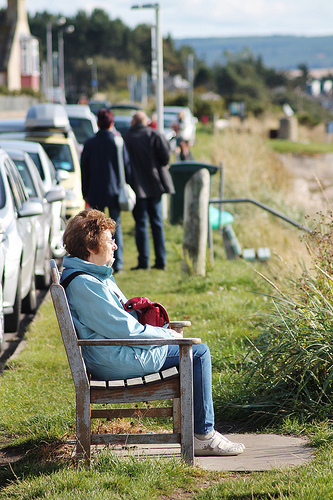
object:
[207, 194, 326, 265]
metal railing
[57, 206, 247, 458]
old lady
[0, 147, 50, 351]
cars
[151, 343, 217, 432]
leg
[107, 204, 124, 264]
leg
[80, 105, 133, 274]
people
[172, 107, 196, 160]
lady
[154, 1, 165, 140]
lamp post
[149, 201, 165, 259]
leg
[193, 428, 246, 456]
feet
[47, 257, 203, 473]
bench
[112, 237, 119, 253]
nose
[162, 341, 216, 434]
jeans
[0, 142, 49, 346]
cars parked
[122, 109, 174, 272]
person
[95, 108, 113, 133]
head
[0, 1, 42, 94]
large buildings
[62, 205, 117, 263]
hair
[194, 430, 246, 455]
shoes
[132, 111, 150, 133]
head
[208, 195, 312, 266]
pipe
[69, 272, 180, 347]
arm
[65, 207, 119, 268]
head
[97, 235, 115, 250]
glasses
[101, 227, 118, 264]
face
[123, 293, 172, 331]
bag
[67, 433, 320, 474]
cement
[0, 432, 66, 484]
shadow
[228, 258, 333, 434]
bush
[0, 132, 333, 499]
ground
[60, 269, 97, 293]
jacket trim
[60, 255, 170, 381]
coat